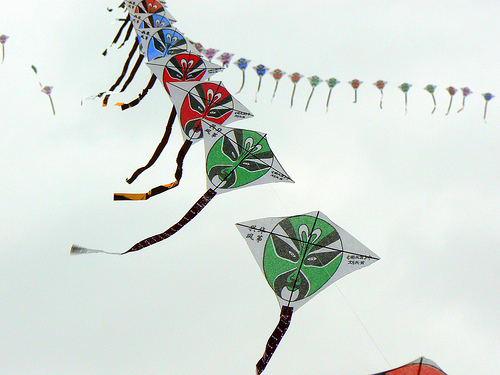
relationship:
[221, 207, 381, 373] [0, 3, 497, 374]
kite flying in sky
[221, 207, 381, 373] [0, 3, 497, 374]
kite lined up in sky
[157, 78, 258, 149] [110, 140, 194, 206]
kite has tail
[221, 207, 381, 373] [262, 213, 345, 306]
kite has design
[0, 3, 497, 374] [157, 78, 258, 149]
sky above kite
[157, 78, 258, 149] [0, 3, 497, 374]
kite flown in sky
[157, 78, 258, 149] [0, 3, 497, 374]
kite in sky